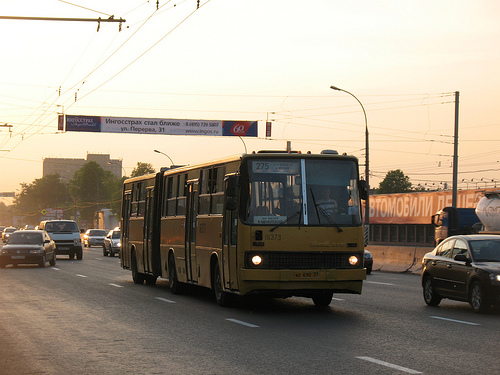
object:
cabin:
[119, 171, 162, 276]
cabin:
[155, 156, 368, 293]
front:
[237, 152, 368, 299]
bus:
[119, 140, 374, 306]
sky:
[0, 0, 500, 187]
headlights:
[248, 251, 267, 266]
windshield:
[253, 163, 362, 225]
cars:
[0, 230, 60, 271]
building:
[32, 149, 132, 185]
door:
[221, 192, 243, 283]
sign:
[166, 116, 222, 136]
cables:
[0, 0, 208, 162]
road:
[0, 237, 500, 375]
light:
[324, 84, 341, 94]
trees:
[66, 162, 118, 211]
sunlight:
[28, 123, 60, 132]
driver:
[280, 181, 306, 223]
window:
[196, 164, 226, 216]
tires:
[208, 249, 230, 307]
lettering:
[344, 197, 379, 205]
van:
[80, 227, 110, 247]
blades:
[281, 209, 336, 227]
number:
[291, 183, 294, 186]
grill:
[289, 253, 295, 256]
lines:
[354, 354, 430, 375]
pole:
[363, 127, 369, 245]